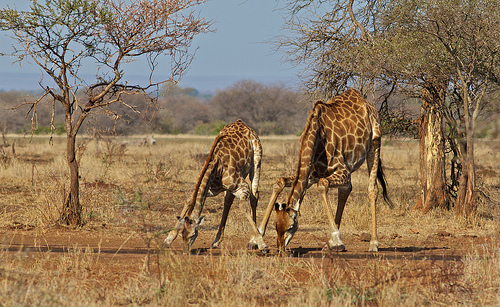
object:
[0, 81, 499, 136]
tree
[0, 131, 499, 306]
ground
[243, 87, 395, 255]
giraffe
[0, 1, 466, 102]
sky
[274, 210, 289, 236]
fur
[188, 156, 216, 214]
neck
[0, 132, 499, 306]
grass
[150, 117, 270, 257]
giraffe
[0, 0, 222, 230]
tree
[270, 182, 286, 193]
knee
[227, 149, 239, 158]
spot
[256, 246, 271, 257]
hoof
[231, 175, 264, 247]
leg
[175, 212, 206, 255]
head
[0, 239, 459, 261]
creek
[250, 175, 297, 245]
leg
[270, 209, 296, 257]
face